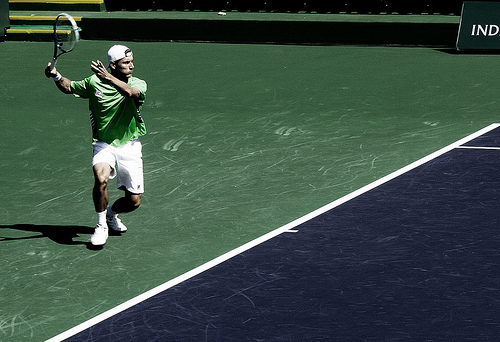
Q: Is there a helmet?
A: No, there are no helmets.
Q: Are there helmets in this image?
A: No, there are no helmets.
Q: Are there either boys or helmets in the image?
A: No, there are no helmets or boys.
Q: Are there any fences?
A: No, there are no fences.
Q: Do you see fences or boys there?
A: No, there are no fences or boys.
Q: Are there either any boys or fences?
A: No, there are no fences or boys.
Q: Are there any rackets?
A: Yes, there is a racket.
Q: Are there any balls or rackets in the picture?
A: Yes, there is a racket.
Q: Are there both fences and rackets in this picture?
A: No, there is a racket but no fences.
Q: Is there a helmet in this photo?
A: No, there are no helmets.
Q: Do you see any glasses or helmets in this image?
A: No, there are no helmets or glasses.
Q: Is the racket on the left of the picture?
A: Yes, the racket is on the left of the image.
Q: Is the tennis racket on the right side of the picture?
A: No, the tennis racket is on the left of the image.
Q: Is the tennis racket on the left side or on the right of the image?
A: The tennis racket is on the left of the image.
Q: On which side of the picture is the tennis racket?
A: The tennis racket is on the left of the image.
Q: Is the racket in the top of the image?
A: Yes, the racket is in the top of the image.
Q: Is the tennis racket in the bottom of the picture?
A: No, the tennis racket is in the top of the image.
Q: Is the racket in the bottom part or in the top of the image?
A: The racket is in the top of the image.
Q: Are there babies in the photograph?
A: No, there are no babies.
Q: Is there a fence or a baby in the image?
A: No, there are no babies or fences.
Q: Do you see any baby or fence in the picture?
A: No, there are no babies or fences.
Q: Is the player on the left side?
A: Yes, the player is on the left of the image.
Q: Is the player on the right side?
A: No, the player is on the left of the image.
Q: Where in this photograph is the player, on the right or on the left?
A: The player is on the left of the image.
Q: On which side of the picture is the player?
A: The player is on the left of the image.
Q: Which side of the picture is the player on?
A: The player is on the left of the image.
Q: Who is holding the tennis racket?
A: The player is holding the tennis racket.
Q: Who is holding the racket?
A: The player is holding the tennis racket.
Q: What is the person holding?
A: The player is holding the racket.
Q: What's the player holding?
A: The player is holding the racket.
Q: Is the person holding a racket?
A: Yes, the player is holding a racket.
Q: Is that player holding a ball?
A: No, the player is holding a racket.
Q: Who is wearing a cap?
A: The player is wearing a cap.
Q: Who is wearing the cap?
A: The player is wearing a cap.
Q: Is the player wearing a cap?
A: Yes, the player is wearing a cap.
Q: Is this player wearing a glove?
A: No, the player is wearing a cap.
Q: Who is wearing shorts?
A: The player is wearing shorts.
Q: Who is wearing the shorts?
A: The player is wearing shorts.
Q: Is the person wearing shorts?
A: Yes, the player is wearing shorts.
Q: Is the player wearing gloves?
A: No, the player is wearing shorts.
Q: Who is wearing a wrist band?
A: The player is wearing a wrist band.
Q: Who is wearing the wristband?
A: The player is wearing a wrist band.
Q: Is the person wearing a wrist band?
A: Yes, the player is wearing a wrist band.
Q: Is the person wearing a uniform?
A: No, the player is wearing a wrist band.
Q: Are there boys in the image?
A: No, there are no boys.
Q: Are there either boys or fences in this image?
A: No, there are no boys or fences.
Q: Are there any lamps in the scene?
A: No, there are no lamps.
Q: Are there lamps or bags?
A: No, there are no lamps or bags.